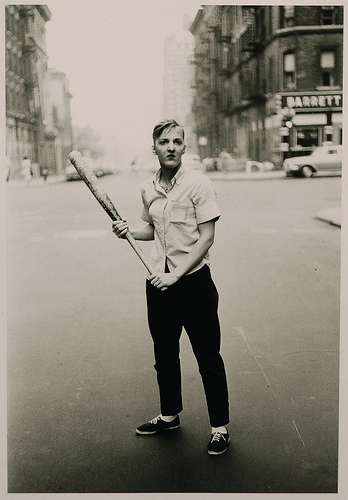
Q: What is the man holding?
A: A bat.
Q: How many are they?
A: 1.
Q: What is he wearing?
A: Sneakers.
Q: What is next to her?
A: Pavement.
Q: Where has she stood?
A: On the road.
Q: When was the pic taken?
A: During the day.